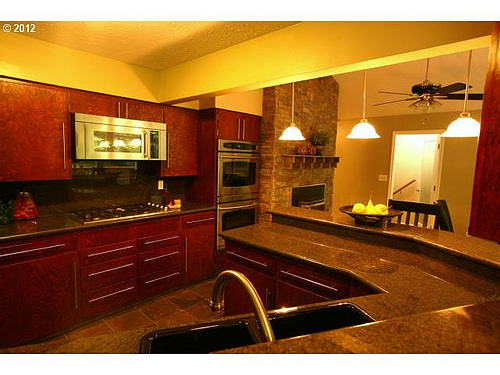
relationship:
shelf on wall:
[264, 129, 367, 189] [267, 159, 294, 209]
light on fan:
[413, 88, 441, 122] [391, 40, 463, 92]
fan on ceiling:
[373, 80, 483, 112] [342, 66, 482, 112]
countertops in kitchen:
[0, 199, 497, 351] [2, 21, 499, 352]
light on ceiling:
[277, 121, 305, 141] [212, 45, 490, 119]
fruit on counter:
[352, 188, 393, 217] [268, 203, 499, 269]